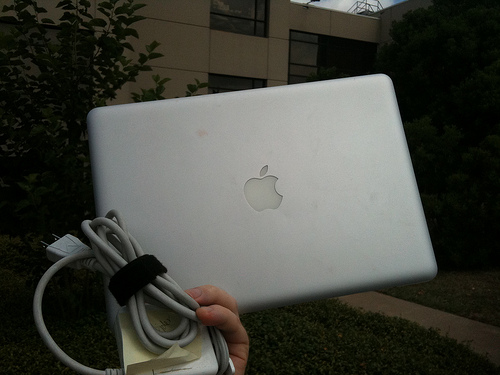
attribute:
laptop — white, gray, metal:
[86, 73, 438, 311]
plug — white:
[27, 208, 235, 370]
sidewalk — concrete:
[349, 285, 499, 356]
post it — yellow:
[114, 303, 204, 368]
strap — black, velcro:
[107, 253, 166, 302]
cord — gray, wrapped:
[26, 206, 230, 374]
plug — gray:
[40, 225, 92, 263]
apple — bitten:
[241, 158, 284, 212]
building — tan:
[44, 49, 453, 133]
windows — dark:
[224, 112, 274, 158]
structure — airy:
[345, 55, 383, 72]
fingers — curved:
[169, 263, 260, 363]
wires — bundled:
[28, 208, 206, 375]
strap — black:
[109, 245, 162, 310]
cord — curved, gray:
[31, 212, 241, 369]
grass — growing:
[226, 288, 481, 367]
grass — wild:
[241, 286, 491, 375]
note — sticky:
[117, 303, 207, 371]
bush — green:
[243, 279, 498, 375]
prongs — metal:
[30, 220, 64, 250]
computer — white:
[45, 70, 443, 328]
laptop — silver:
[69, 70, 451, 363]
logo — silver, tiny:
[239, 157, 299, 242]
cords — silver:
[36, 214, 234, 374]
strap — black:
[104, 238, 168, 297]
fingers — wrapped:
[178, 270, 272, 371]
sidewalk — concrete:
[335, 269, 498, 367]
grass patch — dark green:
[238, 293, 492, 370]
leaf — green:
[147, 52, 164, 60]